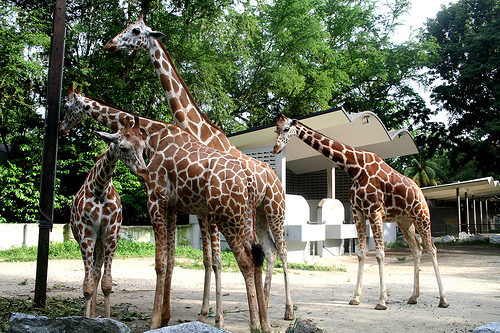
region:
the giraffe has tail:
[206, 119, 318, 286]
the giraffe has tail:
[189, 146, 289, 316]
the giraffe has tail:
[194, 200, 266, 324]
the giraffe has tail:
[131, 115, 313, 325]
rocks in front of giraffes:
[11, 312, 326, 327]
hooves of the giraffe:
[331, 290, 456, 320]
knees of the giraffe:
[63, 272, 129, 307]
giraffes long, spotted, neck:
[274, 129, 364, 160]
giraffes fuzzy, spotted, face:
[262, 115, 302, 159]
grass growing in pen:
[281, 257, 346, 279]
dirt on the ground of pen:
[288, 272, 341, 299]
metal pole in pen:
[5, 10, 70, 322]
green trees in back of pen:
[265, 10, 486, 100]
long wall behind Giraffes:
[0, 213, 196, 254]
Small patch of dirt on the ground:
[353, 319, 370, 329]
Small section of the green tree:
[273, 61, 298, 83]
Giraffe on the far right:
[273, 112, 457, 304]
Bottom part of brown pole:
[31, 275, 52, 307]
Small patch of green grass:
[54, 246, 68, 258]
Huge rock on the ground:
[16, 305, 126, 332]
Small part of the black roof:
[326, 103, 338, 112]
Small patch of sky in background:
[417, 88, 427, 98]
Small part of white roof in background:
[478, 176, 489, 182]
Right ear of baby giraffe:
[96, 127, 120, 145]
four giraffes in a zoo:
[28, 15, 454, 325]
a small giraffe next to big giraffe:
[57, 102, 164, 331]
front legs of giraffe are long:
[345, 207, 396, 310]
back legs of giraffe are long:
[396, 217, 460, 312]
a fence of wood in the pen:
[3, 211, 193, 253]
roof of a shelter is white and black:
[243, 96, 427, 152]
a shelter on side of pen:
[416, 159, 499, 196]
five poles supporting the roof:
[451, 185, 495, 237]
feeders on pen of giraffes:
[283, 189, 349, 262]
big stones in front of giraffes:
[3, 302, 326, 332]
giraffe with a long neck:
[100, 12, 187, 88]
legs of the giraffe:
[143, 245, 280, 325]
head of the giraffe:
[258, 102, 317, 161]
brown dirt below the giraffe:
[324, 303, 360, 329]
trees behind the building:
[221, 41, 296, 88]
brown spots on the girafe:
[356, 163, 405, 207]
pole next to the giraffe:
[9, 133, 77, 253]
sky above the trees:
[402, 6, 442, 31]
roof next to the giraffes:
[326, 90, 396, 137]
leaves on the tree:
[0, 19, 47, 83]